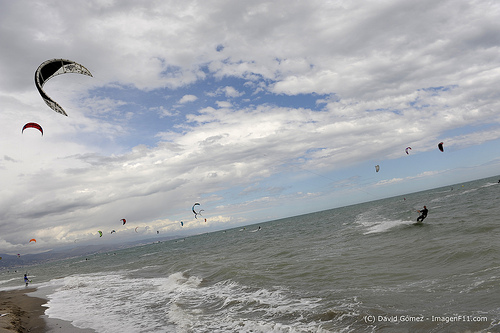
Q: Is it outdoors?
A: Yes, it is outdoors.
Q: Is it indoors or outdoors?
A: It is outdoors.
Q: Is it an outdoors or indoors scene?
A: It is outdoors.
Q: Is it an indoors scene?
A: No, it is outdoors.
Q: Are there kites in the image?
A: Yes, there is a kite.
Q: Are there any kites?
A: Yes, there is a kite.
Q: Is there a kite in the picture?
A: Yes, there is a kite.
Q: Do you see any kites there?
A: Yes, there is a kite.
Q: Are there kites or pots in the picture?
A: Yes, there is a kite.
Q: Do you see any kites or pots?
A: Yes, there is a kite.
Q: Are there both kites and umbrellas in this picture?
A: No, there is a kite but no umbrellas.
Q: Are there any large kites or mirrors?
A: Yes, there is a large kite.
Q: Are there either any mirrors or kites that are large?
A: Yes, the kite is large.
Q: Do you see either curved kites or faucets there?
A: Yes, there is a curved kite.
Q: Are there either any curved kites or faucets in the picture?
A: Yes, there is a curved kite.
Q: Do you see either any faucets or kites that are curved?
A: Yes, the kite is curved.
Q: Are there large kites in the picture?
A: Yes, there is a large kite.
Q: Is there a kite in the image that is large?
A: Yes, there is a kite that is large.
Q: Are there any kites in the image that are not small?
A: Yes, there is a large kite.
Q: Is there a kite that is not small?
A: Yes, there is a large kite.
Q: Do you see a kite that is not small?
A: Yes, there is a large kite.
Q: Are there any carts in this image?
A: No, there are no carts.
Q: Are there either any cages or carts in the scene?
A: No, there are no carts or cages.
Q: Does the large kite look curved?
A: Yes, the kite is curved.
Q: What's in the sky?
A: The kite is in the sky.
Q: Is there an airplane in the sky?
A: No, there is a kite in the sky.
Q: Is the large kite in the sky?
A: Yes, the kite is in the sky.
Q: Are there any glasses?
A: No, there are no glasses.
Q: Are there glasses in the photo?
A: No, there are no glasses.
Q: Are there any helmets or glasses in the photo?
A: No, there are no glasses or helmets.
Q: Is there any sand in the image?
A: Yes, there is sand.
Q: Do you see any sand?
A: Yes, there is sand.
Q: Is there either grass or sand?
A: Yes, there is sand.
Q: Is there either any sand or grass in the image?
A: Yes, there is sand.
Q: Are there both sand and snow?
A: No, there is sand but no snow.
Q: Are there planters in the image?
A: No, there are no planters.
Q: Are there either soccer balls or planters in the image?
A: No, there are no planters or soccer balls.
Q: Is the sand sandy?
A: Yes, the sand is sandy.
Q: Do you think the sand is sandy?
A: Yes, the sand is sandy.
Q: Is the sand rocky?
A: No, the sand is sandy.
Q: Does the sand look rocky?
A: No, the sand is sandy.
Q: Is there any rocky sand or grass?
A: No, there is sand but it is sandy.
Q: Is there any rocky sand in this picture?
A: No, there is sand but it is sandy.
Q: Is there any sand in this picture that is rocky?
A: No, there is sand but it is sandy.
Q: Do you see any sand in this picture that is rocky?
A: No, there is sand but it is sandy.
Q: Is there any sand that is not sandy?
A: No, there is sand but it is sandy.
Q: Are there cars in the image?
A: No, there are no cars.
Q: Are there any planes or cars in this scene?
A: No, there are no cars or planes.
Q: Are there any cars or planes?
A: No, there are no cars or planes.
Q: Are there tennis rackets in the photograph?
A: No, there are no tennis rackets.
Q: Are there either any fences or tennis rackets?
A: No, there are no tennis rackets or fences.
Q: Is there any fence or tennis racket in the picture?
A: No, there are no rackets or fences.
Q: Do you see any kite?
A: Yes, there is a kite.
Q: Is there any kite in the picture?
A: Yes, there is a kite.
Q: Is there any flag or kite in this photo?
A: Yes, there is a kite.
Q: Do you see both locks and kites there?
A: No, there is a kite but no locks.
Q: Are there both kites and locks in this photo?
A: No, there is a kite but no locks.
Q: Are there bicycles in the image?
A: No, there are no bicycles.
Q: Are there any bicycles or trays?
A: No, there are no bicycles or trays.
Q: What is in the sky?
A: The kite is in the sky.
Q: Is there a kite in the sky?
A: Yes, there is a kite in the sky.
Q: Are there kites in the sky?
A: Yes, there is a kite in the sky.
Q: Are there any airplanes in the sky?
A: No, there is a kite in the sky.